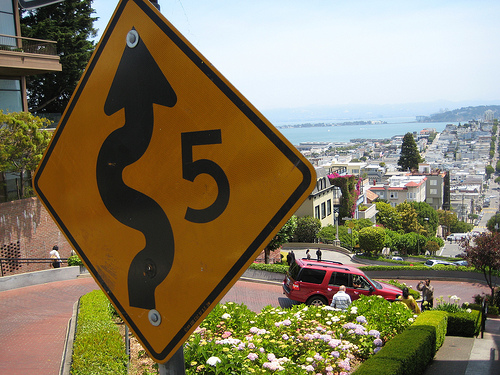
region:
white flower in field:
[198, 354, 225, 366]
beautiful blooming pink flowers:
[297, 326, 351, 367]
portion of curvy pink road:
[24, 285, 97, 322]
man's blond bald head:
[331, 281, 353, 290]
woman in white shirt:
[36, 234, 67, 258]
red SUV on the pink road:
[295, 260, 409, 307]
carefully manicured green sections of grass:
[403, 307, 443, 366]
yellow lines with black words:
[54, 33, 336, 358]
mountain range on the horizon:
[295, 86, 417, 115]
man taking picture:
[408, 270, 457, 321]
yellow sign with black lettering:
[46, 1, 256, 371]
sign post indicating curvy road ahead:
[32, 15, 305, 367]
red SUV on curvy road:
[275, 248, 417, 309]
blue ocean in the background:
[294, 95, 477, 150]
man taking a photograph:
[410, 264, 455, 318]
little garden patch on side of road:
[192, 297, 381, 370]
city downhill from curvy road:
[329, 104, 492, 216]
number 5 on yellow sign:
[165, 110, 235, 232]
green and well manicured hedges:
[380, 307, 450, 370]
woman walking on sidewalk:
[43, 237, 65, 274]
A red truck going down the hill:
[292, 257, 406, 303]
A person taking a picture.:
[414, 274, 457, 327]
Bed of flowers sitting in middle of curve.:
[223, 316, 439, 371]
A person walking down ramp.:
[25, 236, 73, 268]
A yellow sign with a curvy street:
[51, 22, 255, 333]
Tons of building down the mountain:
[342, 133, 492, 232]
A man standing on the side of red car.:
[326, 258, 367, 318]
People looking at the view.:
[306, 243, 340, 263]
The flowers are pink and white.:
[276, 317, 354, 369]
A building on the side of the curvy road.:
[3, 27, 53, 138]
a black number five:
[173, 119, 242, 236]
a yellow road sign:
[26, 23, 308, 340]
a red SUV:
[272, 256, 408, 325]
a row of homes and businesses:
[302, 142, 487, 233]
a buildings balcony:
[0, 17, 77, 76]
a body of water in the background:
[272, 109, 457, 147]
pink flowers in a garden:
[216, 309, 366, 364]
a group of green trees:
[334, 200, 447, 262]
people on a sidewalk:
[302, 242, 332, 263]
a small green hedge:
[377, 307, 449, 371]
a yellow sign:
[36, 4, 315, 371]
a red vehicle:
[281, 253, 409, 306]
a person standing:
[416, 273, 436, 309]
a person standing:
[328, 284, 351, 321]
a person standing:
[392, 279, 423, 319]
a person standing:
[313, 245, 325, 262]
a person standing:
[302, 242, 314, 258]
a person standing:
[47, 243, 67, 263]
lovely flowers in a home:
[75, 280, 411, 371]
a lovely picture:
[1, 0, 496, 374]